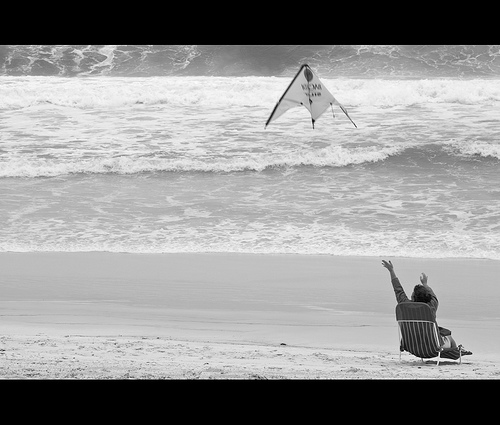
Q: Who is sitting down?
A: A woman.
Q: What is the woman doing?
A: Having her hands up.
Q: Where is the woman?
A: Beach.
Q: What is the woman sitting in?
A: A chair.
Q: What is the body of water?
A: Ocean.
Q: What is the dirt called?
A: Sand.